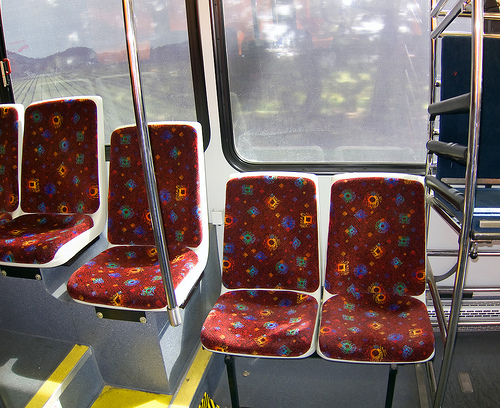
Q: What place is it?
A: It is a field.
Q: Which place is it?
A: It is a field.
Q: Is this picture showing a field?
A: Yes, it is showing a field.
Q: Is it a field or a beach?
A: It is a field.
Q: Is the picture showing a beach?
A: No, the picture is showing a field.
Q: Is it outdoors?
A: Yes, it is outdoors.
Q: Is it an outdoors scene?
A: Yes, it is outdoors.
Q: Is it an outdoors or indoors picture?
A: It is outdoors.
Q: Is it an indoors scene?
A: No, it is outdoors.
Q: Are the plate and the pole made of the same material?
A: Yes, both the plate and the pole are made of metal.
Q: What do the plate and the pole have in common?
A: The material, both the plate and the pole are metallic.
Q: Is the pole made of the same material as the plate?
A: Yes, both the pole and the plate are made of metal.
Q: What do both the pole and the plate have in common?
A: The material, both the pole and the plate are metallic.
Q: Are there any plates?
A: Yes, there is a plate.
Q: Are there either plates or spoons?
A: Yes, there is a plate.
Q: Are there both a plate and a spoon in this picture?
A: No, there is a plate but no spoons.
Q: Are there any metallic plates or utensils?
A: Yes, there is a metal plate.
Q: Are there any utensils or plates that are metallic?
A: Yes, the plate is metallic.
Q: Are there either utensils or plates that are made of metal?
A: Yes, the plate is made of metal.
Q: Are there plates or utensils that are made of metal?
A: Yes, the plate is made of metal.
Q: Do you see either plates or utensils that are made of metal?
A: Yes, the plate is made of metal.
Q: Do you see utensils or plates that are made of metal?
A: Yes, the plate is made of metal.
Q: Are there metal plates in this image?
A: Yes, there is a metal plate.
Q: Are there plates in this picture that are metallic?
A: Yes, there is a plate that is metallic.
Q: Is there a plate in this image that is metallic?
A: Yes, there is a plate that is metallic.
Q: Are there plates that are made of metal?
A: Yes, there is a plate that is made of metal.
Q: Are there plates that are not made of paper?
A: Yes, there is a plate that is made of metal.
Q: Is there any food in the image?
A: No, there is no food.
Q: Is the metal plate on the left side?
A: Yes, the plate is on the left of the image.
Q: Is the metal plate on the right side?
A: No, the plate is on the left of the image.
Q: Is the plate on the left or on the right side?
A: The plate is on the left of the image.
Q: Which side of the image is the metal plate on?
A: The plate is on the left of the image.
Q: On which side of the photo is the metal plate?
A: The plate is on the left of the image.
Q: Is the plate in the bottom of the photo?
A: Yes, the plate is in the bottom of the image.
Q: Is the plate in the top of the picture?
A: No, the plate is in the bottom of the image.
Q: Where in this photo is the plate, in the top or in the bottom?
A: The plate is in the bottom of the image.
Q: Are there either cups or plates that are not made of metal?
A: No, there is a plate but it is made of metal.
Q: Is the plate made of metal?
A: Yes, the plate is made of metal.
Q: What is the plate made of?
A: The plate is made of metal.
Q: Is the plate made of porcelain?
A: No, the plate is made of metal.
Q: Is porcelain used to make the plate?
A: No, the plate is made of metal.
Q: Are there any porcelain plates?
A: No, there is a plate but it is made of metal.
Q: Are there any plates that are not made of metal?
A: No, there is a plate but it is made of metal.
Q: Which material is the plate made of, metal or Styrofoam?
A: The plate is made of metal.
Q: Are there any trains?
A: Yes, there is a train.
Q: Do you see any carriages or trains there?
A: Yes, there is a train.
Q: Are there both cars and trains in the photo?
A: No, there is a train but no cars.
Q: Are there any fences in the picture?
A: No, there are no fences.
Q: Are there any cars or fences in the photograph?
A: No, there are no fences or cars.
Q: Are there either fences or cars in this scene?
A: No, there are no fences or cars.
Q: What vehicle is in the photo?
A: The vehicle is a train.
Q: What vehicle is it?
A: The vehicle is a train.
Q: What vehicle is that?
A: This is a train.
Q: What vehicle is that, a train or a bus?
A: This is a train.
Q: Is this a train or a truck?
A: This is a train.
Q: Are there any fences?
A: No, there are no fences.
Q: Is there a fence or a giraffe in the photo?
A: No, there are no fences or giraffes.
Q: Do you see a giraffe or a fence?
A: No, there are no fences or giraffes.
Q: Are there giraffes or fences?
A: No, there are no fences or giraffes.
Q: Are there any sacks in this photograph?
A: No, there are no sacks.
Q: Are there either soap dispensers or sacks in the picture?
A: No, there are no sacks or soap dispensers.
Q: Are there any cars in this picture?
A: No, there are no cars.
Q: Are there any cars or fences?
A: No, there are no cars or fences.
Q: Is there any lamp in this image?
A: No, there are no lamps.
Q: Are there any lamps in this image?
A: No, there are no lamps.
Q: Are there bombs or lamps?
A: No, there are no lamps or bombs.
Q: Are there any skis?
A: No, there are no skis.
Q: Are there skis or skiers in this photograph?
A: No, there are no skis or skiers.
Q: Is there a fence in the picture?
A: No, there are no fences.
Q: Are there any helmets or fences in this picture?
A: No, there are no fences or helmets.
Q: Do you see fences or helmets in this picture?
A: No, there are no fences or helmets.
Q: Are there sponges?
A: No, there are no sponges.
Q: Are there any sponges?
A: No, there are no sponges.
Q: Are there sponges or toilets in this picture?
A: No, there are no sponges or toilets.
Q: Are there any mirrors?
A: No, there are no mirrors.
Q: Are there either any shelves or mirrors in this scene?
A: No, there are no mirrors or shelves.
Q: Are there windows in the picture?
A: Yes, there is a window.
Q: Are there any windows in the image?
A: Yes, there is a window.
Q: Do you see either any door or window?
A: Yes, there is a window.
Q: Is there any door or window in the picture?
A: Yes, there is a window.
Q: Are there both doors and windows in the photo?
A: No, there is a window but no doors.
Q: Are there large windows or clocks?
A: Yes, there is a large window.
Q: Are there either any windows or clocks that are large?
A: Yes, the window is large.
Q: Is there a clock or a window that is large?
A: Yes, the window is large.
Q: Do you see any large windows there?
A: Yes, there is a large window.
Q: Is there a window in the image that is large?
A: Yes, there is a window that is large.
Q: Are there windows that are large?
A: Yes, there is a window that is large.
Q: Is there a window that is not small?
A: Yes, there is a large window.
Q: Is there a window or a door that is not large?
A: No, there is a window but it is large.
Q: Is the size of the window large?
A: Yes, the window is large.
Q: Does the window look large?
A: Yes, the window is large.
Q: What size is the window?
A: The window is large.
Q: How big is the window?
A: The window is large.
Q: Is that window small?
A: No, the window is large.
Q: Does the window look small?
A: No, the window is large.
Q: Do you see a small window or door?
A: No, there is a window but it is large.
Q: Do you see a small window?
A: No, there is a window but it is large.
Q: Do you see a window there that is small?
A: No, there is a window but it is large.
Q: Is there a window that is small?
A: No, there is a window but it is large.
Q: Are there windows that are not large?
A: No, there is a window but it is large.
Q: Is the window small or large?
A: The window is large.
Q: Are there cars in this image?
A: No, there are no cars.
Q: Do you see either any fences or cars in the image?
A: No, there are no cars or fences.